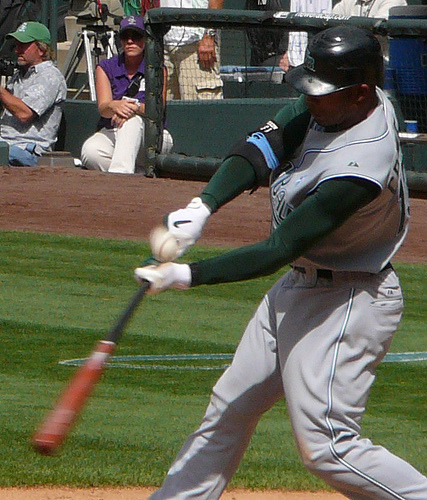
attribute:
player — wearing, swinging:
[135, 22, 425, 499]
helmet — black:
[282, 24, 384, 95]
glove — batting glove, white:
[167, 195, 211, 260]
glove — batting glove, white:
[137, 258, 193, 290]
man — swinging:
[124, 23, 426, 491]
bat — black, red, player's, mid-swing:
[32, 226, 184, 451]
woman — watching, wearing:
[77, 15, 180, 177]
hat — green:
[6, 21, 50, 44]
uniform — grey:
[150, 86, 424, 497]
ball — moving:
[150, 224, 182, 267]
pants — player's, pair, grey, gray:
[148, 253, 422, 495]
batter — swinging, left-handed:
[137, 18, 426, 498]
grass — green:
[2, 232, 427, 483]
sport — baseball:
[3, 0, 419, 493]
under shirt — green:
[187, 81, 379, 286]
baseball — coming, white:
[146, 227, 182, 265]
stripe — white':
[327, 284, 407, 497]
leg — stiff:
[150, 269, 298, 499]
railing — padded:
[140, 1, 426, 185]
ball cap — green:
[5, 21, 53, 43]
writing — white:
[17, 23, 33, 33]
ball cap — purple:
[118, 16, 150, 41]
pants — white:
[78, 115, 177, 178]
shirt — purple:
[93, 51, 164, 131]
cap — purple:
[118, 13, 147, 37]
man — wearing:
[0, 19, 68, 169]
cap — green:
[4, 19, 53, 45]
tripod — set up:
[61, 25, 128, 100]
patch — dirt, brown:
[1, 166, 426, 265]